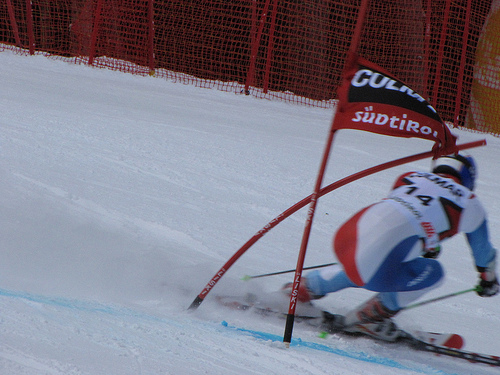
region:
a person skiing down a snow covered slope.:
[219, 146, 499, 371]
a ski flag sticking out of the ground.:
[269, 56, 483, 347]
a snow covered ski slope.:
[1, 44, 498, 372]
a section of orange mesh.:
[0, 0, 498, 137]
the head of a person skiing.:
[426, 136, 486, 210]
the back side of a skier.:
[330, 176, 458, 266]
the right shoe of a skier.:
[341, 306, 374, 333]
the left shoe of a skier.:
[287, 268, 312, 313]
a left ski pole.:
[224, 247, 358, 305]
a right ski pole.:
[323, 266, 495, 340]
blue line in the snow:
[184, 309, 306, 352]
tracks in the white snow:
[50, 151, 207, 230]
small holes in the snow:
[75, 323, 179, 345]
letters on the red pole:
[288, 260, 312, 342]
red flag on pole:
[334, 43, 466, 181]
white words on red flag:
[358, 107, 454, 144]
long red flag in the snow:
[312, 16, 435, 370]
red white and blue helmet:
[415, 101, 485, 186]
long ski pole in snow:
[351, 266, 481, 350]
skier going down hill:
[303, 98, 496, 326]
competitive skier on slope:
[206, 63, 494, 351]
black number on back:
[401, 181, 436, 217]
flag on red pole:
[311, 53, 436, 169]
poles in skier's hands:
[266, 251, 480, 323]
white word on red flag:
[346, 93, 421, 134]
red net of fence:
[184, 37, 236, 89]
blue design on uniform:
[372, 235, 442, 298]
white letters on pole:
[283, 267, 310, 319]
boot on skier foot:
[341, 290, 408, 346]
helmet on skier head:
[428, 146, 483, 189]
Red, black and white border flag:
[327, 49, 459, 149]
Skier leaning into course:
[171, 143, 498, 369]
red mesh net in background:
[3, 3, 415, 56]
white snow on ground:
[26, 104, 198, 267]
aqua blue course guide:
[1, 286, 417, 372]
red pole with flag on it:
[280, 3, 457, 354]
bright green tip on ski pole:
[316, 328, 330, 340]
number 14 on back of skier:
[401, 180, 433, 208]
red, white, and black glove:
[470, 247, 498, 303]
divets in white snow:
[28, 85, 244, 187]